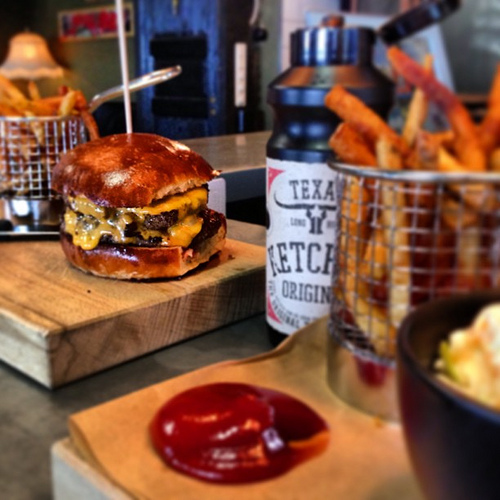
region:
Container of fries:
[327, 43, 498, 368]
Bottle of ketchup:
[264, 26, 394, 343]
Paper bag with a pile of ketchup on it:
[68, 323, 419, 498]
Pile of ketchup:
[140, 379, 332, 484]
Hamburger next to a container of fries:
[47, 128, 228, 279]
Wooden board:
[0, 235, 264, 385]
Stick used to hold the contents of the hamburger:
[112, 18, 137, 138]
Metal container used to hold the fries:
[322, 163, 497, 365]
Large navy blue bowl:
[392, 289, 497, 494]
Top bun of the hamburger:
[51, 133, 218, 213]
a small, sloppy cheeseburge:
[47, 130, 226, 279]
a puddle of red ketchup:
[149, 379, 332, 488]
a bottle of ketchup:
[263, 25, 395, 350]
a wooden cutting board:
[0, 238, 267, 390]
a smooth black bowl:
[392, 288, 499, 499]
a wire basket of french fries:
[322, 45, 497, 363]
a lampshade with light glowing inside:
[0, 24, 65, 81]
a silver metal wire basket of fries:
[0, 62, 183, 199]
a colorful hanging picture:
[55, 3, 137, 44]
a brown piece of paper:
[64, 315, 421, 499]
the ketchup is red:
[200, 401, 272, 455]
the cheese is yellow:
[73, 220, 100, 246]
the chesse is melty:
[68, 215, 97, 252]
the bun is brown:
[84, 142, 140, 203]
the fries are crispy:
[321, 83, 399, 150]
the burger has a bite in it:
[138, 173, 229, 274]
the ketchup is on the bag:
[138, 394, 195, 434]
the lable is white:
[271, 184, 306, 224]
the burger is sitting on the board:
[90, 186, 162, 309]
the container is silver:
[349, 164, 410, 381]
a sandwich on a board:
[27, 125, 265, 378]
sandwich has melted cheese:
[50, 125, 231, 277]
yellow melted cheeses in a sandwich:
[61, 197, 217, 253]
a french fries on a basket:
[0, 65, 95, 235]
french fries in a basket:
[315, 20, 496, 375]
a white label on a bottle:
[250, 155, 340, 337]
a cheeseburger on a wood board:
[55, 120, 226, 280]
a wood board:
[0, 240, 275, 392]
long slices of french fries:
[316, 45, 483, 304]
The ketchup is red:
[147, 378, 330, 488]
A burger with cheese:
[52, 128, 233, 283]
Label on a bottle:
[261, 155, 346, 336]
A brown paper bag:
[65, 316, 427, 498]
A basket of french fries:
[324, 45, 497, 357]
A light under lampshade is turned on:
[1, 28, 68, 85]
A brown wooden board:
[1, 238, 263, 394]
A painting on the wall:
[51, 2, 137, 47]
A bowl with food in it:
[390, 283, 498, 498]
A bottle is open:
[260, 3, 466, 351]